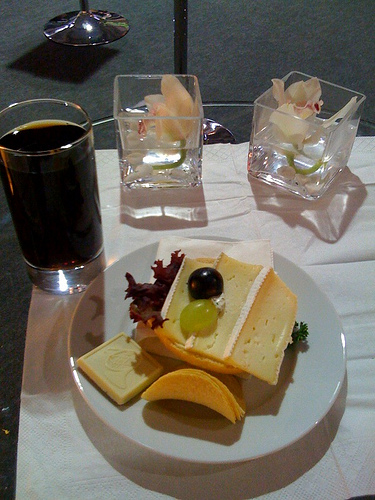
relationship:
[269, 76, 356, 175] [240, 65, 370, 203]
orchid in glass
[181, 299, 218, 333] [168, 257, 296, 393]
grape on top of cheese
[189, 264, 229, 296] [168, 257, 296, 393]
grape on top of cheese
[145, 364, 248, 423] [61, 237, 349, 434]
chips on plate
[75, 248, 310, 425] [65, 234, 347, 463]
food on plate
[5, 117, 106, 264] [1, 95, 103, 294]
soda in glass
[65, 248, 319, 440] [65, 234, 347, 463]
food on plate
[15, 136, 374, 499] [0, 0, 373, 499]
napkin on table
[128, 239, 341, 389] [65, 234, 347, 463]
sandwich on plate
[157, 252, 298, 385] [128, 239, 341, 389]
cheese on sandwich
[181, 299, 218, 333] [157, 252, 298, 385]
grape on cheese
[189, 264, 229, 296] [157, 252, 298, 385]
grape on cheese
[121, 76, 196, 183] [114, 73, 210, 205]
flower floating in glass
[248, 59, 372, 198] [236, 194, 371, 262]
glass topped table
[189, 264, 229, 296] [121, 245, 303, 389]
grape on sandwich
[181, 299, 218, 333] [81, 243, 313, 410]
grape on sandwich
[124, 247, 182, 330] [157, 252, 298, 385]
lettuce under cheese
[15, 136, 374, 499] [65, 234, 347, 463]
napkin under plate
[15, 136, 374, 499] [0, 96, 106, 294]
napkin under glasses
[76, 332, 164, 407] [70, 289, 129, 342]
cheese on plate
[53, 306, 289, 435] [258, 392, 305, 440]
cheese on plate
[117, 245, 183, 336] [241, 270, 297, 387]
lettuce by cheese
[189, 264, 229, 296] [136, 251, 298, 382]
grape on cheese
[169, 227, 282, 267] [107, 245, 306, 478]
napkin on plate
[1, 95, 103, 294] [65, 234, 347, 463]
glass beside plate